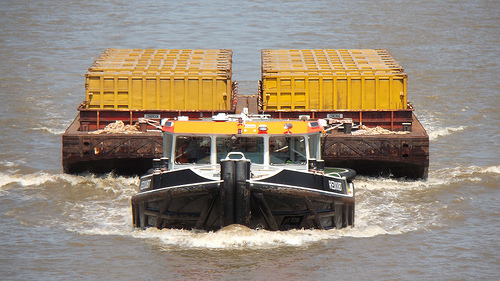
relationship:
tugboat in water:
[61, 44, 428, 235] [3, 0, 500, 281]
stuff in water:
[84, 38, 416, 123] [3, 0, 500, 281]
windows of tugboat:
[172, 131, 308, 164] [61, 44, 428, 235]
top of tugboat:
[163, 118, 324, 136] [61, 44, 428, 235]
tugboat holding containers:
[61, 44, 428, 235] [61, 44, 428, 235]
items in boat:
[59, 111, 428, 139] [61, 44, 428, 235]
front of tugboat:
[62, 111, 434, 234] [61, 44, 428, 235]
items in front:
[59, 111, 428, 139] [62, 111, 434, 234]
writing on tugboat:
[132, 172, 349, 191] [61, 44, 428, 235]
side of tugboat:
[321, 172, 354, 220] [61, 44, 428, 235]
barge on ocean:
[61, 44, 428, 235] [3, 0, 500, 281]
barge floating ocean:
[61, 44, 428, 235] [3, 0, 500, 281]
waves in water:
[132, 227, 366, 252] [3, 0, 500, 281]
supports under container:
[77, 103, 410, 128] [84, 40, 240, 108]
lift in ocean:
[61, 44, 428, 235] [3, 0, 500, 281]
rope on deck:
[90, 120, 146, 137] [61, 115, 431, 172]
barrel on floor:
[340, 118, 354, 134] [332, 121, 415, 132]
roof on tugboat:
[163, 118, 324, 136] [61, 44, 428, 235]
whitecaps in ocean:
[132, 227, 366, 252] [3, 0, 500, 281]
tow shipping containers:
[61, 44, 428, 235] [84, 38, 416, 123]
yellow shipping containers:
[84, 40, 240, 108] [84, 38, 416, 123]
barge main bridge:
[61, 44, 428, 235] [233, 86, 260, 113]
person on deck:
[181, 132, 210, 168] [61, 115, 431, 172]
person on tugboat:
[181, 132, 210, 168] [61, 44, 428, 235]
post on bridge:
[241, 97, 258, 114] [233, 86, 260, 113]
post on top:
[241, 97, 258, 114] [163, 118, 324, 136]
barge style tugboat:
[61, 44, 428, 235] [61, 44, 428, 235]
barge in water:
[61, 44, 428, 235] [3, 0, 500, 281]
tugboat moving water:
[61, 44, 428, 235] [3, 0, 500, 281]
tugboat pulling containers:
[61, 44, 428, 235] [260, 44, 400, 118]